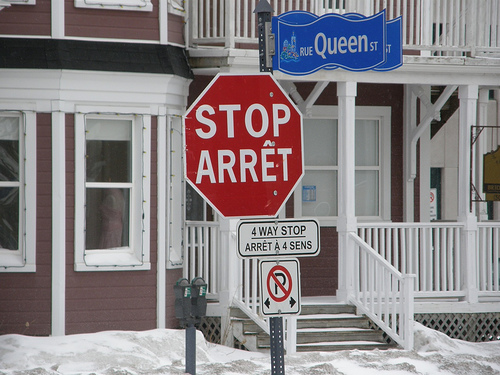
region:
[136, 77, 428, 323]
stop sign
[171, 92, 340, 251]
stop sign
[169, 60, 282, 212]
stop sign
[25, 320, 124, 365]
large area of white snow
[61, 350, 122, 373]
small bumps in the snow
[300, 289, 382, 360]
steps on front of building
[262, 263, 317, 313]
red circle on white square sign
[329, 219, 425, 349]
white railing on porch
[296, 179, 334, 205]
small square sign in window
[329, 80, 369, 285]
long white post on porch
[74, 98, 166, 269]
christmas light in front of window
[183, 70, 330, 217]
large red and white sign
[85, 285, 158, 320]
red bricks on wall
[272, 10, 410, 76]
BLUE SIGN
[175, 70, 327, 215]
RED STOP SIGN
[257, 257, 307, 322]
NO PARKING SIGN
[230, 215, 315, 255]
4 WAY STOP SIGN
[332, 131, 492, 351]
WHITE PORCH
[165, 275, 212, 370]
2 PARKING METERS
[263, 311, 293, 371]
METAL SIGN POLE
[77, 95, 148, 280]
WHITE WINDOW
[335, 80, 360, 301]
WHITE HOUSE SUPPORT COLUMN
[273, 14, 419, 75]
QUEEN ST ON SIGN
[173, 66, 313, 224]
A red stop sign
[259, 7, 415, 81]
A blue street sign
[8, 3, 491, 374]
Photo was taken in the daytime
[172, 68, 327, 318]
White traffic signs are below the red stop sign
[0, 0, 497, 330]
A house is in the background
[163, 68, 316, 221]
Red stop sign says "STOP ARRET"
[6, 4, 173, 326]
The house is brown and white in color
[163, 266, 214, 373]
A parking meter is behind the street traffic signs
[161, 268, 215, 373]
The parking meter is gray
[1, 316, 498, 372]
The ground is covered in ice and snow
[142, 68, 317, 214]
red and white stop sign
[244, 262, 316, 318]
no parking street sign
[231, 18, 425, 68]
blue and white street sign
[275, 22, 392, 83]
Rue Queens St. street sign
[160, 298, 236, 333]
two gray parking meters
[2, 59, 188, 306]
bay window on house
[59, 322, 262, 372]
snow covered sidewalk and ground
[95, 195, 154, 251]
pink women's dress in the window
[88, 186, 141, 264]
mannequin in the window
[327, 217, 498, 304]
front porch of house